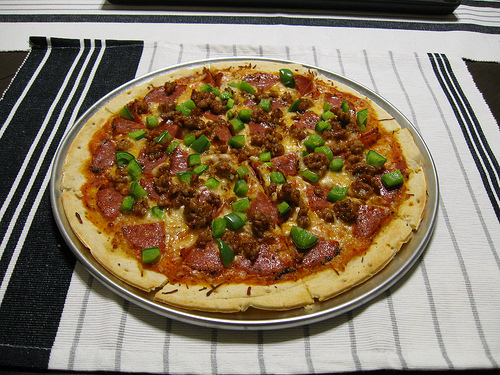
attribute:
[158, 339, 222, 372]
pattern — Striped